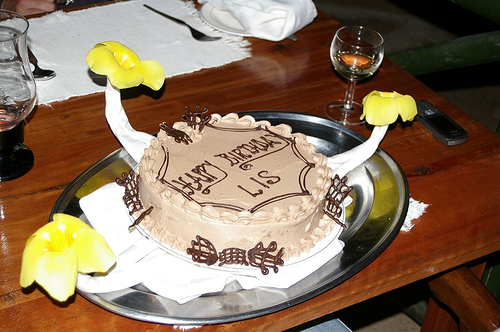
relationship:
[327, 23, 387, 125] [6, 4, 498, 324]
glass on table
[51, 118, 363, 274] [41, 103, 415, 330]
cake over pan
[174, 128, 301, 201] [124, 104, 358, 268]
lettering on cake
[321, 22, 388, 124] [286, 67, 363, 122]
wine glass on table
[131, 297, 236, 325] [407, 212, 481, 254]
silver platter on table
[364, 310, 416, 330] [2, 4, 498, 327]
carpet in room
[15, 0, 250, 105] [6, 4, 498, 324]
cloth on table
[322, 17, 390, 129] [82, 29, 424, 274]
glass next cake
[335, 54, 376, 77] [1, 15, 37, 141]
liquid in glass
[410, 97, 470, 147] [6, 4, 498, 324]
phone on table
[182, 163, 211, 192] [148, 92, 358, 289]
word on cake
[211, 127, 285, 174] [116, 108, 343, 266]
writing on cake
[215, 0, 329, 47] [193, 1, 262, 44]
napkin on plate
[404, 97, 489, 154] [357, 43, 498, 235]
cellphone on table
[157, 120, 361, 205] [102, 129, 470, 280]
cake on platter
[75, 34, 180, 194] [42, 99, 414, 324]
flower on platter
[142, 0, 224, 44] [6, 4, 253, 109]
fork on mat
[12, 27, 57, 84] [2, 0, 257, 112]
spoon on place mat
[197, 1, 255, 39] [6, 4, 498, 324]
plate on table